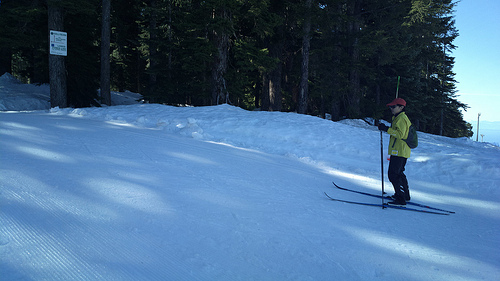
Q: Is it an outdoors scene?
A: Yes, it is outdoors.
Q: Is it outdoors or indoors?
A: It is outdoors.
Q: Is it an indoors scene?
A: No, it is outdoors.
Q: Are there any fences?
A: No, there are no fences.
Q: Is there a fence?
A: No, there are no fences.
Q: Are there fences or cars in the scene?
A: No, there are no fences or cars.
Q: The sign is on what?
A: The sign is on the tree.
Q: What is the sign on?
A: The sign is on the tree.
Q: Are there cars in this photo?
A: No, there are no cars.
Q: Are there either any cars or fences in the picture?
A: No, there are no cars or fences.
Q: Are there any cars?
A: No, there are no cars.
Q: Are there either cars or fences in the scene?
A: No, there are no cars or fences.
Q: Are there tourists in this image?
A: No, there are no tourists.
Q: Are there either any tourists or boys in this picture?
A: No, there are no tourists or boys.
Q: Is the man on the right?
A: Yes, the man is on the right of the image.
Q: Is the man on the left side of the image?
A: No, the man is on the right of the image.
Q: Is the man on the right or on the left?
A: The man is on the right of the image.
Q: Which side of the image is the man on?
A: The man is on the right of the image.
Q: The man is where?
A: The man is at the trees.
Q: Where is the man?
A: The man is at the trees.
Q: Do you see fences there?
A: No, there are no fences.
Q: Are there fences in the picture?
A: No, there are no fences.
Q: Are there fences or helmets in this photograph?
A: No, there are no fences or helmets.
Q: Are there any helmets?
A: No, there are no helmets.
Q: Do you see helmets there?
A: No, there are no helmets.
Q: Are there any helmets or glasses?
A: No, there are no helmets or glasses.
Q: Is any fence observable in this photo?
A: No, there are no fences.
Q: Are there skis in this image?
A: Yes, there are skis.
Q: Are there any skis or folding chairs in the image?
A: Yes, there are skis.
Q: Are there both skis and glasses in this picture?
A: No, there are skis but no glasses.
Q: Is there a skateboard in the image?
A: No, there are no skateboards.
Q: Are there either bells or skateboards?
A: No, there are no skateboards or bells.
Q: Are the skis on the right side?
A: Yes, the skis are on the right of the image.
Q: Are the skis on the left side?
A: No, the skis are on the right of the image.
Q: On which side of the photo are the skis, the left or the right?
A: The skis are on the right of the image.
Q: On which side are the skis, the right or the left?
A: The skis are on the right of the image.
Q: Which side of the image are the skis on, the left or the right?
A: The skis are on the right of the image.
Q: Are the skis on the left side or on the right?
A: The skis are on the right of the image.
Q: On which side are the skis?
A: The skis are on the right of the image.